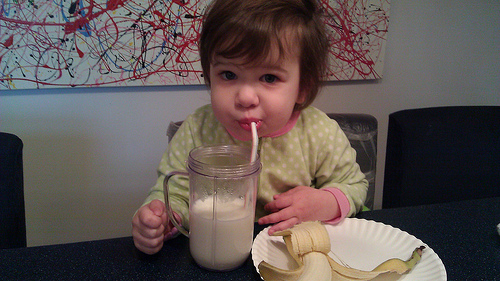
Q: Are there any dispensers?
A: No, there are no dispensers.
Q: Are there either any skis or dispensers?
A: No, there are no dispensers or skis.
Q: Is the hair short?
A: Yes, the hair is short.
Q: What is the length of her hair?
A: The hair is short.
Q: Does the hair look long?
A: No, the hair is short.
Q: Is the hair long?
A: No, the hair is short.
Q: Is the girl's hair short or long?
A: The hair is short.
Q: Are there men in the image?
A: No, there are no men.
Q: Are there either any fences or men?
A: No, there are no men or fences.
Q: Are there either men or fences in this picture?
A: No, there are no men or fences.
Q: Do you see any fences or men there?
A: No, there are no men or fences.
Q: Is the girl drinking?
A: Yes, the girl is drinking.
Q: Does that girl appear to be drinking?
A: Yes, the girl is drinking.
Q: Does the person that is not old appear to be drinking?
A: Yes, the girl is drinking.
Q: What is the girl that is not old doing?
A: The girl is drinking.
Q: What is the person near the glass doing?
A: The girl is drinking.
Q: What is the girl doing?
A: The girl is drinking.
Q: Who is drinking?
A: The girl is drinking.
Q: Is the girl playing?
A: No, the girl is drinking.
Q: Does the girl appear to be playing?
A: No, the girl is drinking.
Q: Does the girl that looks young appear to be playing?
A: No, the girl is drinking.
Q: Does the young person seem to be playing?
A: No, the girl is drinking.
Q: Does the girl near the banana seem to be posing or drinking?
A: The girl is drinking.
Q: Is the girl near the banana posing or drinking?
A: The girl is drinking.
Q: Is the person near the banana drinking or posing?
A: The girl is drinking.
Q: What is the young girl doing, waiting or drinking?
A: The girl is drinking.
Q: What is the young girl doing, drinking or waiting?
A: The girl is drinking.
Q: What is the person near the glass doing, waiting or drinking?
A: The girl is drinking.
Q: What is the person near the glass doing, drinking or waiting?
A: The girl is drinking.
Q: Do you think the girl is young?
A: Yes, the girl is young.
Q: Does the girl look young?
A: Yes, the girl is young.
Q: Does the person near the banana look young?
A: Yes, the girl is young.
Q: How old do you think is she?
A: The girl is young.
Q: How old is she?
A: The girl is young.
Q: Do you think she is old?
A: No, the girl is young.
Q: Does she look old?
A: No, the girl is young.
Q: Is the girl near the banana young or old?
A: The girl is young.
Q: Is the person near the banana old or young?
A: The girl is young.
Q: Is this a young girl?
A: Yes, this is a young girl.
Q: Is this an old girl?
A: No, this is a young girl.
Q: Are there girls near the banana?
A: Yes, there is a girl near the banana.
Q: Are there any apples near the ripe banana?
A: No, there is a girl near the banana.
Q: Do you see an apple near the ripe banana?
A: No, there is a girl near the banana.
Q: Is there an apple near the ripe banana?
A: No, there is a girl near the banana.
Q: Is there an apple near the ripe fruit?
A: No, there is a girl near the banana.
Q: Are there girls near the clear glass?
A: Yes, there is a girl near the glass.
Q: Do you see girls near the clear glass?
A: Yes, there is a girl near the glass.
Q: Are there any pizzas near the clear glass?
A: No, there is a girl near the glass.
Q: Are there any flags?
A: No, there are no flags.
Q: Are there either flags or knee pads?
A: No, there are no flags or knee pads.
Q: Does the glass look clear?
A: Yes, the glass is clear.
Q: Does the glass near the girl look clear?
A: Yes, the glass is clear.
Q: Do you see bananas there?
A: Yes, there is a banana.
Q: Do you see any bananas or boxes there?
A: Yes, there is a banana.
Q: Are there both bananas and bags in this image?
A: No, there is a banana but no bags.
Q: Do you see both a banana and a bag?
A: No, there is a banana but no bags.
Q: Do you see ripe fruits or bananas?
A: Yes, there is a ripe banana.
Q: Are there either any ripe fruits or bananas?
A: Yes, there is a ripe banana.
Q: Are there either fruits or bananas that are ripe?
A: Yes, the banana is ripe.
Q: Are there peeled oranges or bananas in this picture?
A: Yes, there is a peeled banana.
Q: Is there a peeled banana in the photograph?
A: Yes, there is a peeled banana.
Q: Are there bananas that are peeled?
A: Yes, there is a banana that is peeled.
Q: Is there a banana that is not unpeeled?
A: Yes, there is an peeled banana.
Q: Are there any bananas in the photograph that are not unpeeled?
A: Yes, there is an peeled banana.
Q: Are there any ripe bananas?
A: Yes, there is a ripe banana.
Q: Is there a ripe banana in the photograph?
A: Yes, there is a ripe banana.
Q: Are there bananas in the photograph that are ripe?
A: Yes, there is a banana that is ripe.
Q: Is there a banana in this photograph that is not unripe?
A: Yes, there is an ripe banana.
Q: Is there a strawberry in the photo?
A: No, there are no strawberries.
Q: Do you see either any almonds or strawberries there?
A: No, there are no strawberries or almonds.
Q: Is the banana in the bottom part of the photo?
A: Yes, the banana is in the bottom of the image.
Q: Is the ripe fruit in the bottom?
A: Yes, the banana is in the bottom of the image.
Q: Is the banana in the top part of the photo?
A: No, the banana is in the bottom of the image.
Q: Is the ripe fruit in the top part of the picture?
A: No, the banana is in the bottom of the image.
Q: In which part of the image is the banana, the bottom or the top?
A: The banana is in the bottom of the image.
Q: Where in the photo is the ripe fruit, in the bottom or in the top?
A: The banana is in the bottom of the image.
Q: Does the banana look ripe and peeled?
A: Yes, the banana is ripe and peeled.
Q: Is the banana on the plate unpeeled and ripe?
A: No, the banana is ripe but peeled.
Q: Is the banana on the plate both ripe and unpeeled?
A: No, the banana is ripe but peeled.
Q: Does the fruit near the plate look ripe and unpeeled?
A: No, the banana is ripe but peeled.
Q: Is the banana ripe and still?
A: Yes, the banana is ripe and still.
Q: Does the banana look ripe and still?
A: Yes, the banana is ripe and still.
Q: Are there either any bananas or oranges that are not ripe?
A: No, there is a banana but it is ripe.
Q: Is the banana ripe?
A: Yes, the banana is ripe.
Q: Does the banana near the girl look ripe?
A: Yes, the banana is ripe.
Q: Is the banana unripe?
A: No, the banana is ripe.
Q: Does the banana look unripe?
A: No, the banana is ripe.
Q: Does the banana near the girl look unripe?
A: No, the banana is ripe.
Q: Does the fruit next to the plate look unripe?
A: No, the banana is ripe.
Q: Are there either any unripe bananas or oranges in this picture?
A: No, there is a banana but it is ripe.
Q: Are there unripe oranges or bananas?
A: No, there is a banana but it is ripe.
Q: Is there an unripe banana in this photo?
A: No, there is a banana but it is ripe.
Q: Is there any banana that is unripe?
A: No, there is a banana but it is ripe.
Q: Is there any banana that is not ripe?
A: No, there is a banana but it is ripe.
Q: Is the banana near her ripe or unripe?
A: The banana is ripe.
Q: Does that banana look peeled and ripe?
A: Yes, the banana is peeled and ripe.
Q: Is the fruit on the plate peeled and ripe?
A: Yes, the banana is peeled and ripe.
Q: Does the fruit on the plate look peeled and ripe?
A: Yes, the banana is peeled and ripe.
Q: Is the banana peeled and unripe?
A: No, the banana is peeled but ripe.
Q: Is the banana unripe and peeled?
A: No, the banana is peeled but ripe.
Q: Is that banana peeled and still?
A: Yes, the banana is peeled and still.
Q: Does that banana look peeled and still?
A: Yes, the banana is peeled and still.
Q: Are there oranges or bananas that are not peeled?
A: No, there is a banana but it is peeled.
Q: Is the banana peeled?
A: Yes, the banana is peeled.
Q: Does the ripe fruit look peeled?
A: Yes, the banana is peeled.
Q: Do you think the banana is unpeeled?
A: No, the banana is peeled.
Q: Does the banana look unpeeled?
A: No, the banana is peeled.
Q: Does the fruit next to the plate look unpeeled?
A: No, the banana is peeled.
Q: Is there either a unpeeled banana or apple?
A: No, there is a banana but it is peeled.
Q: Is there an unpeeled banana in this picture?
A: No, there is a banana but it is peeled.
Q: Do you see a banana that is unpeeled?
A: No, there is a banana but it is peeled.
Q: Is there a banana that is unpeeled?
A: No, there is a banana but it is peeled.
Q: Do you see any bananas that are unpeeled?
A: No, there is a banana but it is peeled.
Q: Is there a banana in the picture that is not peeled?
A: No, there is a banana but it is peeled.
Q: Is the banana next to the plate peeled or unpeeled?
A: The banana is peeled.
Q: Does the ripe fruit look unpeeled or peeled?
A: The banana is peeled.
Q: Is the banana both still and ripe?
A: Yes, the banana is still and ripe.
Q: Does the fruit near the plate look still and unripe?
A: No, the banana is still but ripe.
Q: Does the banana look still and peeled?
A: Yes, the banana is still and peeled.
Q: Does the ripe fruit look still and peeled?
A: Yes, the banana is still and peeled.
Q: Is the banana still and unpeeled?
A: No, the banana is still but peeled.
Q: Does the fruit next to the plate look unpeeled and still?
A: No, the banana is still but peeled.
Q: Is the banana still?
A: Yes, the banana is still.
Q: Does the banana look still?
A: Yes, the banana is still.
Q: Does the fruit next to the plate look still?
A: Yes, the banana is still.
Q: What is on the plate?
A: The banana is on the plate.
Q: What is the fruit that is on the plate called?
A: The fruit is a banana.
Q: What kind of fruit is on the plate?
A: The fruit is a banana.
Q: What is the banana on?
A: The banana is on the plate.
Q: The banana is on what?
A: The banana is on the plate.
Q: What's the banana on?
A: The banana is on the plate.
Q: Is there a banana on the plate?
A: Yes, there is a banana on the plate.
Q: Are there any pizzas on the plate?
A: No, there is a banana on the plate.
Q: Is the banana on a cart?
A: No, the banana is on the plate.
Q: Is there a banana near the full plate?
A: Yes, there is a banana near the plate.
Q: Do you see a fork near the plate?
A: No, there is a banana near the plate.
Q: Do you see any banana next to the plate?
A: Yes, there is a banana next to the plate.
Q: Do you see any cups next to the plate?
A: No, there is a banana next to the plate.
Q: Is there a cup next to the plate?
A: No, there is a banana next to the plate.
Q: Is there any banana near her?
A: Yes, there is a banana near the girl.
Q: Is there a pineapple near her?
A: No, there is a banana near the girl.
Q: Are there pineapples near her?
A: No, there is a banana near the girl.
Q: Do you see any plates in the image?
A: Yes, there is a plate.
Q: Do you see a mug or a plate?
A: Yes, there is a plate.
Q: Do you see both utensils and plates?
A: No, there is a plate but no utensils.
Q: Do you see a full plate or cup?
A: Yes, there is a full plate.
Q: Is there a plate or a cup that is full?
A: Yes, the plate is full.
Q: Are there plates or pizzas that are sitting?
A: Yes, the plate is sitting.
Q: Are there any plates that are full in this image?
A: Yes, there is a full plate.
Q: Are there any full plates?
A: Yes, there is a full plate.